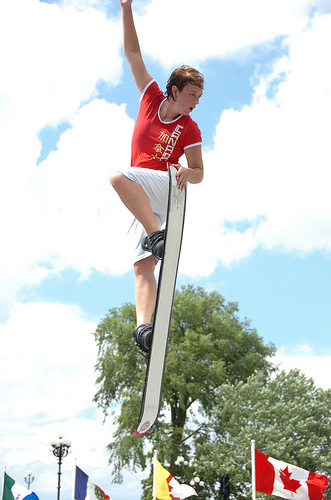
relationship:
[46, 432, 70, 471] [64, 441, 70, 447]
lights with globe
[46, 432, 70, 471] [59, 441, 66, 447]
lights with globe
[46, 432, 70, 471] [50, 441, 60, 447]
lights with globe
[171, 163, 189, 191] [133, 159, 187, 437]
hand on board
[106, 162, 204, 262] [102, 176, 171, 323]
shorts on legs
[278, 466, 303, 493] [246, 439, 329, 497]
maple leaf on flag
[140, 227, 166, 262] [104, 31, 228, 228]
foot of boy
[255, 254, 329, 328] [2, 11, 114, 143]
sky has clouds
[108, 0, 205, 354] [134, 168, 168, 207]
girl wearing white shorts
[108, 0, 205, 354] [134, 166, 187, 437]
girl performs on ski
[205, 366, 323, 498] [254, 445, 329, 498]
tree obscured by flag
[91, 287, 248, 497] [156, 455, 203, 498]
tree obscured by flag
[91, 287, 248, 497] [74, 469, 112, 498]
tree obscured by flag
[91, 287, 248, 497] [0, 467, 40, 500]
tree obscured by country flag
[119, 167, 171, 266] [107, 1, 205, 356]
shorts on a boy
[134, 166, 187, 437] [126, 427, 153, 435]
ski with red trim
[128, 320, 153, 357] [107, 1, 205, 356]
foot of boy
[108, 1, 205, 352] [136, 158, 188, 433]
girl on snowboard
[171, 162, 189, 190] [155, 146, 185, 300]
hand on snowboard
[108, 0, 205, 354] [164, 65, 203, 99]
girl has hair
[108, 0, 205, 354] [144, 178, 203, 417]
girl on snowboard